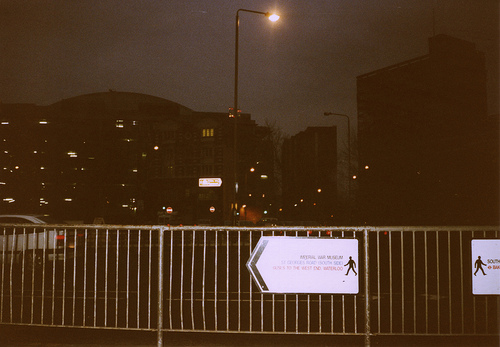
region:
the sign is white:
[234, 228, 404, 329]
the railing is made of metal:
[74, 223, 178, 326]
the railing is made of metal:
[204, 210, 293, 345]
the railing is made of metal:
[338, 213, 473, 345]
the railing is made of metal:
[150, 200, 260, 345]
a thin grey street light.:
[223, 0, 288, 173]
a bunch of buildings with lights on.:
[0, 80, 195, 223]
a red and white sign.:
[190, 170, 230, 195]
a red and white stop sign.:
[157, 201, 178, 224]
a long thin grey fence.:
[1, 217, 236, 344]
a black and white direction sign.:
[244, 237, 365, 294]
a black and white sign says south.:
[456, 227, 498, 307]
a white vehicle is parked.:
[1, 191, 99, 286]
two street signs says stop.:
[152, 197, 237, 229]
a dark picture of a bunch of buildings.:
[0, 0, 499, 345]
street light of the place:
[228, 6, 287, 120]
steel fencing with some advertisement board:
[36, 225, 499, 324]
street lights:
[39, 123, 339, 216]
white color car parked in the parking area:
[3, 187, 71, 272]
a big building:
[353, 40, 493, 215]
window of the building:
[192, 125, 217, 142]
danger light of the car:
[56, 228, 66, 250]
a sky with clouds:
[268, 38, 340, 98]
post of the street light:
[230, 61, 243, 222]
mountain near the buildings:
[85, 90, 181, 137]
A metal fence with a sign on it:
[6, 215, 427, 342]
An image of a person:
[338, 252, 360, 281]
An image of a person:
[468, 244, 490, 284]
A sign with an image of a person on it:
[254, 234, 365, 296]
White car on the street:
[13, 221, 93, 266]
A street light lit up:
[215, 2, 287, 234]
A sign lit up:
[196, 174, 228, 189]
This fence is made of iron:
[10, 218, 171, 336]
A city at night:
[75, 78, 346, 234]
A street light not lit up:
[312, 104, 359, 176]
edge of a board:
[286, 224, 313, 247]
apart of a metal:
[144, 300, 163, 321]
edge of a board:
[274, 278, 294, 295]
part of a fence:
[221, 308, 237, 325]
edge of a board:
[291, 287, 311, 307]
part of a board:
[257, 275, 292, 317]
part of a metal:
[155, 275, 165, 293]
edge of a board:
[282, 283, 294, 295]